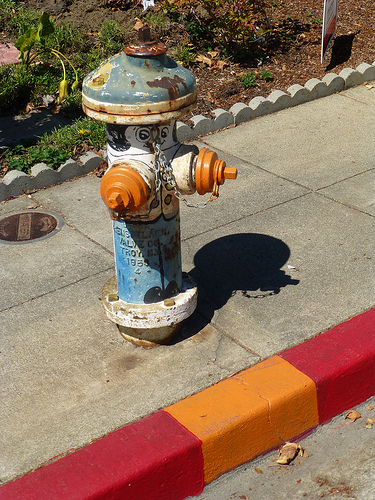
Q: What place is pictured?
A: It is a sidewalk.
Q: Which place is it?
A: It is a sidewalk.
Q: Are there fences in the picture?
A: No, there are no fences.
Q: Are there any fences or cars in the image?
A: No, there are no fences or cars.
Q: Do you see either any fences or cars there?
A: No, there are no fences or cars.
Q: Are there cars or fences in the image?
A: No, there are no fences or cars.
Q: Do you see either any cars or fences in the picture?
A: No, there are no fences or cars.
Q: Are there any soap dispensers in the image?
A: No, there are no soap dispensers.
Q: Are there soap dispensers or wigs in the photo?
A: No, there are no soap dispensers or wigs.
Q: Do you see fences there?
A: No, there are no fences.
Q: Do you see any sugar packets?
A: No, there are no sugar packets.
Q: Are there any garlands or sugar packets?
A: No, there are no sugar packets or garlands.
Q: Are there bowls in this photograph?
A: No, there are no bowls.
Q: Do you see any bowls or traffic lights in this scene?
A: No, there are no bowls or traffic lights.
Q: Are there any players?
A: No, there are no players.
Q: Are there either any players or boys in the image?
A: No, there are no players or boys.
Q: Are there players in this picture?
A: No, there are no players.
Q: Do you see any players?
A: No, there are no players.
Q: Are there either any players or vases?
A: No, there are no players or vases.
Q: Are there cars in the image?
A: No, there are no cars.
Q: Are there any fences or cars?
A: No, there are no cars or fences.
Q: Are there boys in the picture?
A: No, there are no boys.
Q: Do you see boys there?
A: No, there are no boys.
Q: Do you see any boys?
A: No, there are no boys.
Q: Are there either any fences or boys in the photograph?
A: No, there are no boys or fences.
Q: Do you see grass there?
A: Yes, there is grass.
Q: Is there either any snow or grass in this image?
A: Yes, there is grass.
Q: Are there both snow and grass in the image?
A: No, there is grass but no snow.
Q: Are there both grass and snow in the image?
A: No, there is grass but no snow.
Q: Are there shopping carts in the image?
A: No, there are no shopping carts.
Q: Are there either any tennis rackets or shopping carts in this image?
A: No, there are no shopping carts or tennis rackets.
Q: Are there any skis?
A: No, there are no skis.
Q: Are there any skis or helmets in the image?
A: No, there are no skis or helmets.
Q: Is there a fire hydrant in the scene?
A: Yes, there is a fire hydrant.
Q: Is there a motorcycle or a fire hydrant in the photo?
A: Yes, there is a fire hydrant.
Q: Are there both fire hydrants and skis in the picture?
A: No, there is a fire hydrant but no skis.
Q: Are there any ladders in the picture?
A: No, there are no ladders.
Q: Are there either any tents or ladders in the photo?
A: No, there are no ladders or tents.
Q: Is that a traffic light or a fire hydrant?
A: That is a fire hydrant.